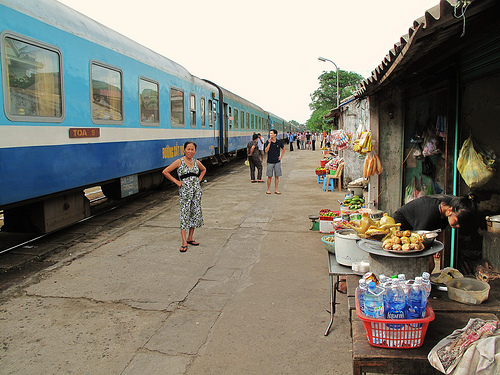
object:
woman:
[161, 141, 207, 253]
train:
[0, 0, 305, 237]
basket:
[353, 275, 438, 351]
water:
[358, 271, 432, 348]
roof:
[353, 0, 500, 101]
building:
[356, 0, 498, 272]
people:
[246, 133, 266, 184]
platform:
[0, 132, 455, 374]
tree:
[305, 66, 364, 133]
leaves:
[322, 94, 327, 99]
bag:
[455, 134, 494, 189]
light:
[317, 55, 341, 107]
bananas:
[376, 154, 382, 174]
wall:
[374, 91, 500, 253]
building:
[322, 92, 360, 189]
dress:
[176, 157, 205, 231]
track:
[0, 134, 293, 280]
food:
[347, 212, 425, 255]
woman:
[391, 192, 482, 239]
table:
[322, 235, 374, 338]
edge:
[326, 250, 357, 275]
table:
[344, 273, 500, 375]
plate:
[356, 240, 446, 260]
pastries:
[382, 229, 425, 254]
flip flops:
[179, 244, 189, 253]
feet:
[179, 241, 187, 252]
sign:
[69, 128, 101, 139]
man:
[263, 128, 286, 194]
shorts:
[265, 162, 282, 178]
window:
[1, 31, 67, 125]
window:
[88, 58, 126, 126]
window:
[138, 73, 161, 127]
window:
[169, 85, 185, 129]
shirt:
[264, 138, 285, 164]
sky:
[55, 0, 440, 127]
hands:
[176, 180, 183, 189]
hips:
[183, 188, 190, 189]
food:
[314, 156, 428, 254]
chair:
[325, 159, 345, 193]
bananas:
[353, 196, 358, 200]